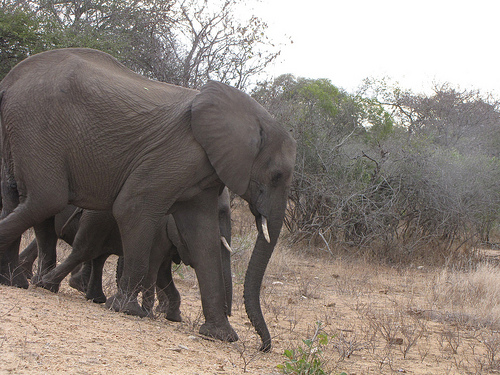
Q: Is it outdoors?
A: Yes, it is outdoors.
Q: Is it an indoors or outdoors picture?
A: It is outdoors.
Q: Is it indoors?
A: No, it is outdoors.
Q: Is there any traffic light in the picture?
A: No, there are no traffic lights.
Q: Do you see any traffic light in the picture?
A: No, there are no traffic lights.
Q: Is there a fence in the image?
A: No, there are no fences.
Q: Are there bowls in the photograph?
A: No, there are no bowls.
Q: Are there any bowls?
A: No, there are no bowls.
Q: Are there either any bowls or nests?
A: No, there are no bowls or nests.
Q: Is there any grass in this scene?
A: Yes, there is grass.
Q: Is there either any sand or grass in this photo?
A: Yes, there is grass.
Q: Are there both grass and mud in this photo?
A: No, there is grass but no mud.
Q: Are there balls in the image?
A: No, there are no balls.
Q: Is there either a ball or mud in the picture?
A: No, there are no balls or mud.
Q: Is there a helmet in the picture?
A: No, there are no helmets.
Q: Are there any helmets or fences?
A: No, there are no helmets or fences.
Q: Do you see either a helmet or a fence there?
A: No, there are no helmets or fences.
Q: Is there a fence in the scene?
A: No, there are no fences.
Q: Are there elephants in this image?
A: Yes, there is an elephant.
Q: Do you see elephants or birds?
A: Yes, there is an elephant.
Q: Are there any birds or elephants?
A: Yes, there is an elephant.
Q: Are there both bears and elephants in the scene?
A: No, there is an elephant but no bears.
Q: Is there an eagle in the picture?
A: No, there are no eagles.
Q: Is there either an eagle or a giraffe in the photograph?
A: No, there are no eagles or giraffes.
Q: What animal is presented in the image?
A: The animal is an elephant.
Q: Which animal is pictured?
A: The animal is an elephant.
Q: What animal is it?
A: The animal is an elephant.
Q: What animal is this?
A: That is an elephant.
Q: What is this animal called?
A: That is an elephant.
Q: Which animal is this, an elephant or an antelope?
A: That is an elephant.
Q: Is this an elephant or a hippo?
A: This is an elephant.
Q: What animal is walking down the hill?
A: The elephant is walking down the hill.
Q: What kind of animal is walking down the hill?
A: The animal is an elephant.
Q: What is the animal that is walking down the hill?
A: The animal is an elephant.